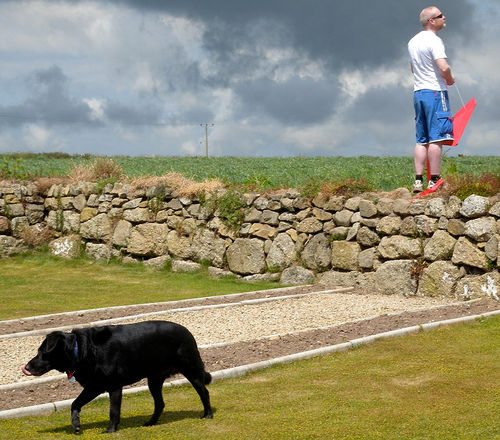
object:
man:
[407, 4, 454, 194]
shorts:
[412, 88, 453, 145]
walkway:
[1, 284, 500, 417]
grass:
[0, 246, 292, 320]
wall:
[0, 178, 500, 300]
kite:
[447, 99, 477, 148]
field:
[0, 150, 500, 195]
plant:
[216, 193, 246, 235]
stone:
[226, 236, 266, 275]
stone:
[111, 220, 132, 247]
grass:
[0, 313, 499, 439]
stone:
[51, 382, 60, 390]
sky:
[1, 2, 499, 157]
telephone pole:
[204, 122, 209, 159]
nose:
[24, 363, 32, 373]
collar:
[73, 338, 80, 361]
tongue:
[23, 365, 30, 378]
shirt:
[408, 28, 450, 91]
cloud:
[231, 73, 346, 129]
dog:
[23, 320, 214, 432]